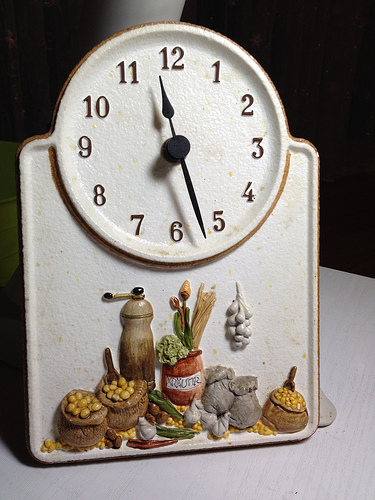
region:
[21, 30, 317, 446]
that is a clock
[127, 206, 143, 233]
that is a digit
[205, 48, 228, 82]
that is a digit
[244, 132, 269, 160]
that is a digit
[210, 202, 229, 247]
that is a digit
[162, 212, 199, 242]
that is a digit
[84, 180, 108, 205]
that is a digit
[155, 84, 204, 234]
the hands of the clock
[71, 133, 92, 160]
that is a digit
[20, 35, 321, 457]
the clock is white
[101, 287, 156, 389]
an image of a grinder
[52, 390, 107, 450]
an image of a bag of potatoes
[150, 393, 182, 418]
an image of a cut green bean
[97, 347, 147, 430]
an image of potatoes with a dipper in it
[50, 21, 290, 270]
the face of an analog clock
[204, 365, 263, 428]
an impression of two gray bags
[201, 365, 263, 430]
an image of two bags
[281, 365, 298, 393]
a wooden paddle in a bag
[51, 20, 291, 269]
a brown and white clock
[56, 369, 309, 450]
three bags of potatoes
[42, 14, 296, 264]
a round analog clock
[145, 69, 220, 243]
the hour and minute hand of clock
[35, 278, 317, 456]
a ceramic design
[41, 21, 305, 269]
a ceramic clock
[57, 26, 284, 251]
numerical numbers on the clock hour hand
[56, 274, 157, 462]
graphical design on the ceramic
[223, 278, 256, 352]
a design of a garlic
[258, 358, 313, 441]
a design of a bag of fruits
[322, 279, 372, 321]
a flat white table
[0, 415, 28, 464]
shadows from the ceramic clock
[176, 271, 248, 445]
this is a clock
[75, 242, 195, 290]
the clock is white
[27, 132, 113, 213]
the clock is dirty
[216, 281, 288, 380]
this is a sac of garlic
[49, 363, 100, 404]
these are many potatoes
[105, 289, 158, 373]
this is a pepper grinder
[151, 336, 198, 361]
this is a vegetable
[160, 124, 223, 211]
this is a clock hand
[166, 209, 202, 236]
the hand is black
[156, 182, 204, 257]
the numbers are black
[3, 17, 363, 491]
round clock on white surface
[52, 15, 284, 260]
white face with black hands and numbers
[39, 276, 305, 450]
raised decorations of containers and foods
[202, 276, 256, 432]
twisted stalks of white garlic above burlap sacks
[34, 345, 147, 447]
open bags of yellow foods with measuring spoon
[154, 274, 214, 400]
open red container of lettuce, mushrooms and pasta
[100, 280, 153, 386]
large gray and brown pepper grinder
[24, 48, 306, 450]
yellow specks across white surface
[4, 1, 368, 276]
white form behind clock in darkness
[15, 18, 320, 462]
brown trim along edge of clock and panel